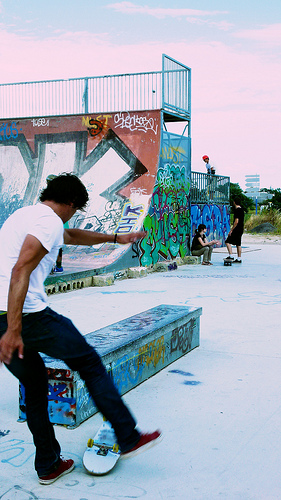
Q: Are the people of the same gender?
A: No, they are both male and female.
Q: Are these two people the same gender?
A: No, they are both male and female.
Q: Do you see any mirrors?
A: No, there are no mirrors.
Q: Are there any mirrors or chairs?
A: No, there are no mirrors or chairs.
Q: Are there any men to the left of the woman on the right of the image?
A: Yes, there is a man to the left of the woman.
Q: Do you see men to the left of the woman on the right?
A: Yes, there is a man to the left of the woman.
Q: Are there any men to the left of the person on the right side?
A: Yes, there is a man to the left of the woman.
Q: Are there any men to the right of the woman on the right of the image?
A: No, the man is to the left of the woman.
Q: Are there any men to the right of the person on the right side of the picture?
A: No, the man is to the left of the woman.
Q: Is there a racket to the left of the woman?
A: No, there is a man to the left of the woman.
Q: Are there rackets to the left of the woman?
A: No, there is a man to the left of the woman.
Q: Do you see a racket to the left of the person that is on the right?
A: No, there is a man to the left of the woman.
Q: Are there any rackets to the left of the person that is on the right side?
A: No, there is a man to the left of the woman.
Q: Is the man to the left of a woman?
A: Yes, the man is to the left of a woman.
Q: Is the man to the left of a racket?
A: No, the man is to the left of a woman.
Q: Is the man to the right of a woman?
A: No, the man is to the left of a woman.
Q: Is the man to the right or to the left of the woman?
A: The man is to the left of the woman.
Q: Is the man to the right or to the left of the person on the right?
A: The man is to the left of the woman.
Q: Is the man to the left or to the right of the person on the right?
A: The man is to the left of the woman.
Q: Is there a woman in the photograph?
A: Yes, there is a woman.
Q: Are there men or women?
A: Yes, there is a woman.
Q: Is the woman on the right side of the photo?
A: Yes, the woman is on the right of the image.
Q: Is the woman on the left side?
A: No, the woman is on the right of the image.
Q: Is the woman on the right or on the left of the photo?
A: The woman is on the right of the image.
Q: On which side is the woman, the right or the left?
A: The woman is on the right of the image.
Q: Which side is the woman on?
A: The woman is on the right of the image.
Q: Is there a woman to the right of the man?
A: Yes, there is a woman to the right of the man.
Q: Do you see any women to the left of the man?
A: No, the woman is to the right of the man.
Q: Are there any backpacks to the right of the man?
A: No, there is a woman to the right of the man.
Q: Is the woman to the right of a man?
A: Yes, the woman is to the right of a man.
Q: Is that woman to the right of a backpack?
A: No, the woman is to the right of a man.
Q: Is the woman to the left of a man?
A: No, the woman is to the right of a man.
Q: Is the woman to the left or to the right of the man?
A: The woman is to the right of the man.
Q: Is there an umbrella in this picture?
A: No, there are no umbrellas.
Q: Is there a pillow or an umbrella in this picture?
A: No, there are no umbrellas or pillows.